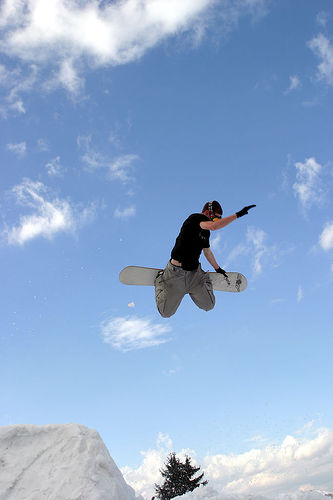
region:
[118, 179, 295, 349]
Snowboarder doing a trick in the air.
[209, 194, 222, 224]
Goggles on the man's head.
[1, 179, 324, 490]
Photo taken in the afternoon.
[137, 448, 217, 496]
Tree sticking up from the bottom.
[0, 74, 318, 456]
Blue sky with white clouds.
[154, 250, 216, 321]
Grey pants on the snowboarder.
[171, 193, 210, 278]
Black shirt on the snowboarder.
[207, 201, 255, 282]
Gloves on the man's hands.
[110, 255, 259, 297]
The snowboard is white.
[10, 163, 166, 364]
White clouds in the sky.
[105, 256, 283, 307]
Snowboarder doing tricks.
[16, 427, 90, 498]
The snow is white.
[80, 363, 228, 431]
The sky is blue.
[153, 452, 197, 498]
The tree is green.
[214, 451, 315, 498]
The clouds are white.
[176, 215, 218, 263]
The shirt is black.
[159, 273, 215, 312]
The pants are grey.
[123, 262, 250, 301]
The snowboard is white.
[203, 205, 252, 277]
The gloves are black.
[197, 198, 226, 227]
The man is wearing goggles.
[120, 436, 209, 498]
tall tree in the snow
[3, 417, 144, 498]
mounds of white snow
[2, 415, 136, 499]
mounds of snow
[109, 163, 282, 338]
a person snowboarding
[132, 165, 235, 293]
a person wearing goggles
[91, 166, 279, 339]
a person snowboarding with a grey snowboard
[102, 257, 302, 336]
a grey snowboard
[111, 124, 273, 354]
a person with a black shirt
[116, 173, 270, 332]
a person wearing grey pants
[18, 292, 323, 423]
sky is blue and cloudy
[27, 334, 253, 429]
sky is blue and cloudy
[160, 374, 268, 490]
sky is blue and cloudy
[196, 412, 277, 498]
sky is blue and cloudy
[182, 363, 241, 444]
sky is blue and cloudy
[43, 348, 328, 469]
sky is blue and cloudy